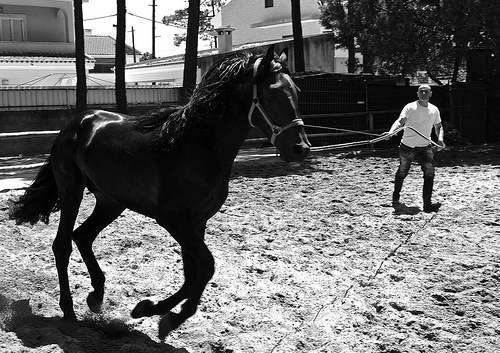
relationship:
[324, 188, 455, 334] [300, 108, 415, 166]
shadow of rope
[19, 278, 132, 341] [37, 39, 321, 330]
shadow of horse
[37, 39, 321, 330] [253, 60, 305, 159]
horse has harness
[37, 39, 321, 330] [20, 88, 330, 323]
horse in field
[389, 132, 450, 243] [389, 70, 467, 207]
jeans on man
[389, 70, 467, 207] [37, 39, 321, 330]
man and horse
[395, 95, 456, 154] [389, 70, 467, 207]
shirt on man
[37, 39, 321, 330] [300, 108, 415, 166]
horse with rope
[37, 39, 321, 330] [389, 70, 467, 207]
horse with man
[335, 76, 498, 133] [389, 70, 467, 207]
fence behind man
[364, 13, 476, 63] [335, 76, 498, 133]
tree behind fence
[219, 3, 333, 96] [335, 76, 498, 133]
house behind fence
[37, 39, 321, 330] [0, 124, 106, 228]
horse has tail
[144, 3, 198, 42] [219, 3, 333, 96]
line between house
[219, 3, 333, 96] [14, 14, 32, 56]
house with window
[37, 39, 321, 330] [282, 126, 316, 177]
horse has nose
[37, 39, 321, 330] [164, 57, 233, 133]
horse has mane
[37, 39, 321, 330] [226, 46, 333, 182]
horse has head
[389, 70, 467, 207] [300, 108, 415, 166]
man with rope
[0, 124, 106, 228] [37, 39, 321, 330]
tail of horse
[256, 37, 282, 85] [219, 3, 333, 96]
ear of house